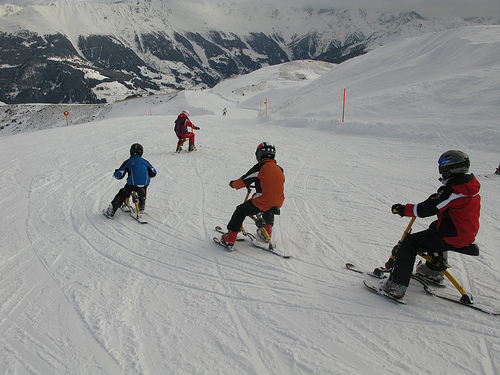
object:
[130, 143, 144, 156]
helmet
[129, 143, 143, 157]
head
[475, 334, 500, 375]
marks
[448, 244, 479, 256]
seat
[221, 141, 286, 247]
boy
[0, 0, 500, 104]
mountain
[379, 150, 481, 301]
boy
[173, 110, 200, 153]
boy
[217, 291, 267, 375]
stripes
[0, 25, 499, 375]
snow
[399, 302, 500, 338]
tracks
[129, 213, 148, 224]
ski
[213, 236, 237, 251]
ski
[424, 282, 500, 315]
skis